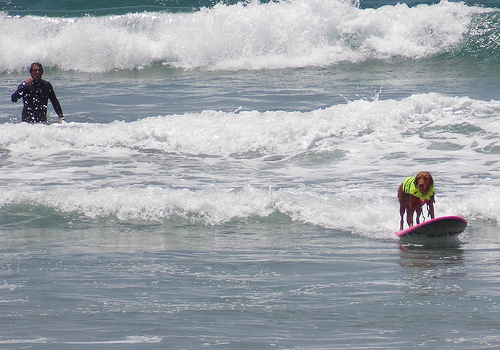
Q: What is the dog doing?
A: Surfing.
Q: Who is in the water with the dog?
A: A man in a black wetsuit.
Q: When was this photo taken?
A: During the day.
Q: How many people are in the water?
A: One.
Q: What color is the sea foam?
A: White.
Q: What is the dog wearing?
A: A life jacket.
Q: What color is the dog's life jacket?
A: Bright green with black stripes.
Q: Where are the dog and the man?
A: In the water.